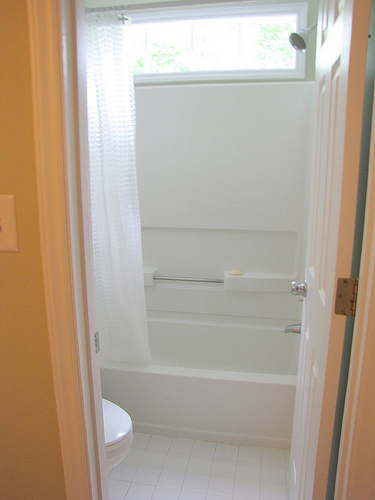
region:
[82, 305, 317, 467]
bathtub is white and shallow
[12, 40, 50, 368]
painted orange wall outside bathroom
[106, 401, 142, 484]
white toilet in bathroom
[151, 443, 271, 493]
white floor in bathroom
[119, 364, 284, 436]
white tub wall in bathroom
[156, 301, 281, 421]
white tub in bathroom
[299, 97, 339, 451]
white door of bathroom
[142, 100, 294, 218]
white wall in shower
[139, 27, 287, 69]
window in bathroom above tub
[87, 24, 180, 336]
white opaque shower curtain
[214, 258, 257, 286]
peach soap in white tub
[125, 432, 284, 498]
floor tiles are white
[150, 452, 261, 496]
floor tiles are white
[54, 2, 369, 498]
Bathroom is white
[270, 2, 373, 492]
Door of bathroom is open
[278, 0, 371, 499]
Door of bathroom is brown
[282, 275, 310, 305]
Knob of dood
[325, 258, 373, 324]
Hinge in the center of door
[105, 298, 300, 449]
Bathtub in the bathroom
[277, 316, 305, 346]
Faucet of bathtub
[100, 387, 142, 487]
Toilet is white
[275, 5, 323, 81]
Shower heard of bathroom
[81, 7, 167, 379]
White curtain of bathtub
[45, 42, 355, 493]
a nice view of an empty bathroom.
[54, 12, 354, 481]
a view of an open bathroom.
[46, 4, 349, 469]
view of a clean bathroom.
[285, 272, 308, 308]
door knob to bathroom door.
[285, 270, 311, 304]
metal door knob of door.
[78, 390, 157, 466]
part of a toilet.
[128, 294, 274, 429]
white bath tub area.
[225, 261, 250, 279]
a white bar of soap.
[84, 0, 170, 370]
a clean shower curtain.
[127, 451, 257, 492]
white tile floor to bathroom.